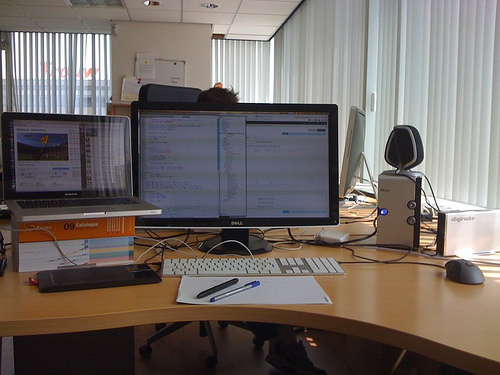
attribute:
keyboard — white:
[162, 257, 345, 275]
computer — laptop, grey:
[0, 112, 160, 218]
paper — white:
[183, 275, 324, 307]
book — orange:
[17, 225, 135, 237]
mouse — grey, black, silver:
[444, 258, 485, 286]